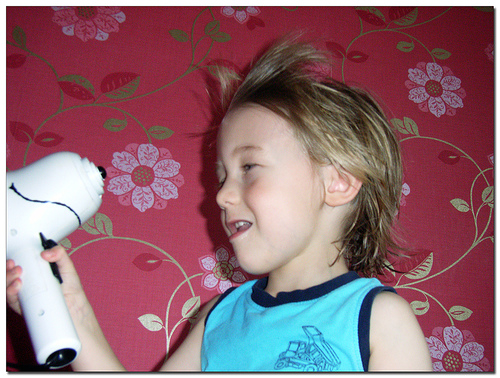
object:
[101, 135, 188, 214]
flower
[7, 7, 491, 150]
wall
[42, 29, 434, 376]
boy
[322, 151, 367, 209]
ear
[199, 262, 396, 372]
shirt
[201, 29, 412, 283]
hair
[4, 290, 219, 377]
shadow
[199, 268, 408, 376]
tank top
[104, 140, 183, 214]
flower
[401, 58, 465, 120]
flower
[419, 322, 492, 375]
flower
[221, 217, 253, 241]
mouth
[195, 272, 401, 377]
shirt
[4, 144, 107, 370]
hair dryer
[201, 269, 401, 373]
t-shirt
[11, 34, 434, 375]
child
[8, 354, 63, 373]
wire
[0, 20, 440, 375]
child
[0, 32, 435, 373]
child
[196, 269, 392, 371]
shirt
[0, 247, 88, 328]
hand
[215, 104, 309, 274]
face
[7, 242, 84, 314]
hand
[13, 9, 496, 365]
background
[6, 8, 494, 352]
wall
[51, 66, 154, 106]
leaves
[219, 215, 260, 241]
mouth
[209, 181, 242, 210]
nose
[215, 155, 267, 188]
eyes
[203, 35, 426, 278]
hair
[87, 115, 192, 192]
air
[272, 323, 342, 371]
design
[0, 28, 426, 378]
child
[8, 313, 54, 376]
shadow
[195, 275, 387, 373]
top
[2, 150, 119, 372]
hair dryer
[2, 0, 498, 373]
cloth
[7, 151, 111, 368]
blower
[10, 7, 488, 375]
surface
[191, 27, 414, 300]
her hair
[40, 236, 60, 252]
button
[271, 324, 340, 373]
drawing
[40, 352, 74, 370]
cord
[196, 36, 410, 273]
grey hair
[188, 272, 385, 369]
child wearing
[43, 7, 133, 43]
flower designs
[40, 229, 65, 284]
black button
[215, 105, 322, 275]
face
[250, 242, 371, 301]
neck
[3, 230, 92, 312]
hands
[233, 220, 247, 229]
teeth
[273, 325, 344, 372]
truck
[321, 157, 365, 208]
ear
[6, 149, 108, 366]
dryer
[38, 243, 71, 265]
thumb